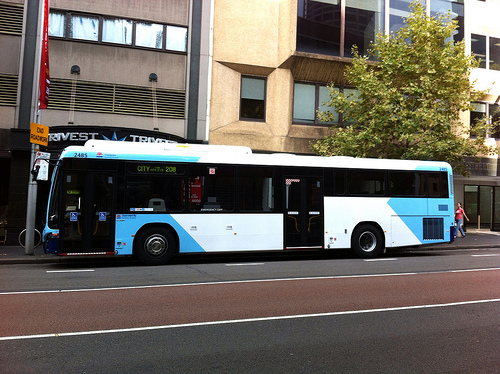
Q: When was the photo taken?
A: Daytime.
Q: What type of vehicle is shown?
A: Bus.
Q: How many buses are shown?
A: One.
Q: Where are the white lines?
A: Street.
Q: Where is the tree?
A: Behind the bus.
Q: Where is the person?
A: Sidewalk.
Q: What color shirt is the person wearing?
A: Red.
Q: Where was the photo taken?
A: On the street.